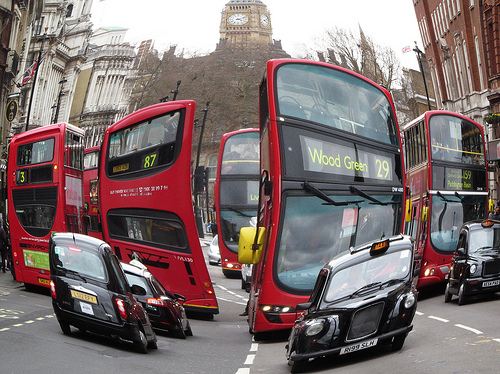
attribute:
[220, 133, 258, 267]
bus — red, double decker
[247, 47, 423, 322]
buses — double decker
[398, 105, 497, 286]
buses — double decker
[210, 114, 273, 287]
buses — double decker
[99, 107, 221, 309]
buses — double decker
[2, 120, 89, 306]
buses — double decker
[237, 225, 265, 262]
mirror — yellow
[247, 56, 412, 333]
bus — red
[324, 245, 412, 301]
window — black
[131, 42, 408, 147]
tree — leafless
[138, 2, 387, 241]
building — brown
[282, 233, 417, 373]
car — black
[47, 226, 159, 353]
car — black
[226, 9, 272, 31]
clock — white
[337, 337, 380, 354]
license plate — white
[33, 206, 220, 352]
cars — dark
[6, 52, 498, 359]
buses — red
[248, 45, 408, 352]
bus — double decker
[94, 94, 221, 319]
bus — double decker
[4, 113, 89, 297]
bus — double decker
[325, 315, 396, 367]
license — yellow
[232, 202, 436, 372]
car — black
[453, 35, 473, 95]
window — white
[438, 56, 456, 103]
window — white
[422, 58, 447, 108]
window — white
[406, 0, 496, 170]
building — brick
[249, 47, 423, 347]
bus — 87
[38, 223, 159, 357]
car — black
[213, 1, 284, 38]
panels — square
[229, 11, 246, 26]
numbers — dark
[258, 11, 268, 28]
hands — dark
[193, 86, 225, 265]
pole — curved